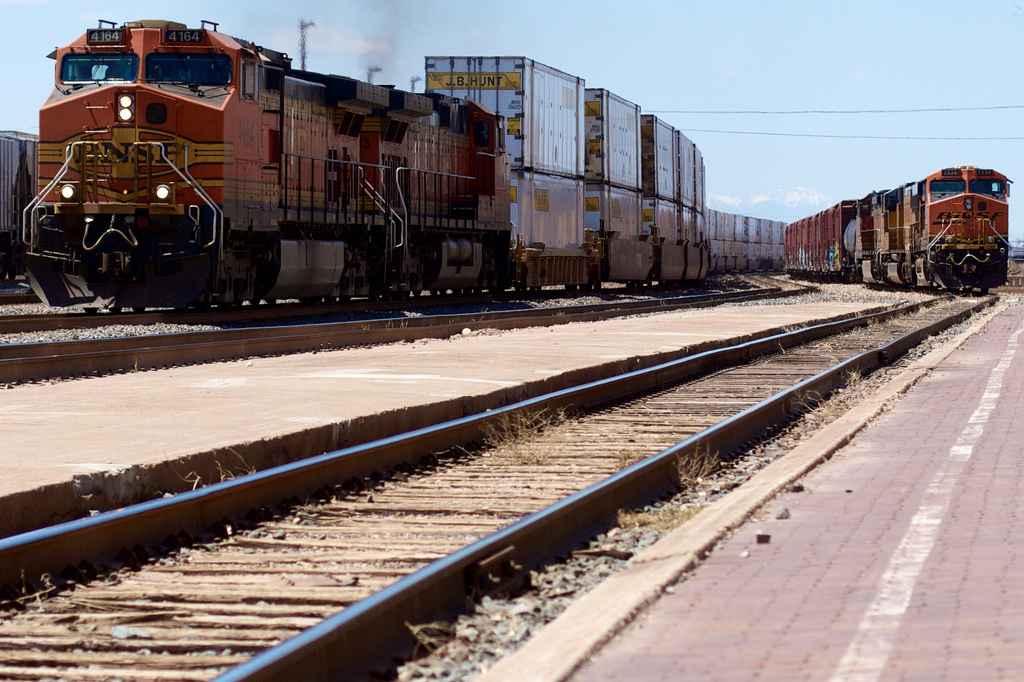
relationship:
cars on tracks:
[22, 20, 788, 296] [2, 260, 692, 381]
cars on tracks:
[414, 60, 791, 296] [2, 260, 692, 381]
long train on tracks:
[787, 163, 1016, 299] [0, 269, 1010, 680]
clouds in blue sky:
[619, 25, 794, 77] [540, 11, 1012, 202]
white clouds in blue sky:
[860, 61, 956, 138] [559, 8, 1019, 218]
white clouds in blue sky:
[844, 61, 956, 105] [559, 8, 1019, 218]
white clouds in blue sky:
[844, 61, 956, 105] [0, 1, 1024, 242]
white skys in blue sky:
[726, 95, 825, 135] [0, 1, 1024, 242]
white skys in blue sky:
[788, 0, 1024, 94] [522, 3, 1017, 223]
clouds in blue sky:
[619, 25, 794, 64] [522, 3, 1017, 223]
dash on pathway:
[892, 326, 1001, 680] [596, 298, 1018, 628]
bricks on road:
[983, 405, 1019, 503] [610, 323, 1022, 622]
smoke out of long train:
[349, 0, 406, 80] [785, 165, 1015, 297]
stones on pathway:
[748, 474, 813, 558] [468, 299, 1024, 681]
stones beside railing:
[386, 539, 617, 679] [237, 317, 911, 678]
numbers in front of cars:
[82, 25, 209, 48] [22, 20, 788, 296]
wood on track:
[19, 601, 239, 678] [0, 286, 1002, 678]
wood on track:
[405, 455, 646, 481] [0, 286, 1002, 678]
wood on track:
[755, 357, 801, 378] [0, 286, 1002, 678]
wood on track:
[481, 455, 562, 481] [0, 286, 1002, 678]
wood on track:
[868, 321, 908, 332] [0, 286, 1002, 678]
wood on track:
[712, 357, 852, 378] [0, 286, 1002, 678]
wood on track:
[234, 522, 424, 571] [0, 286, 1002, 678]